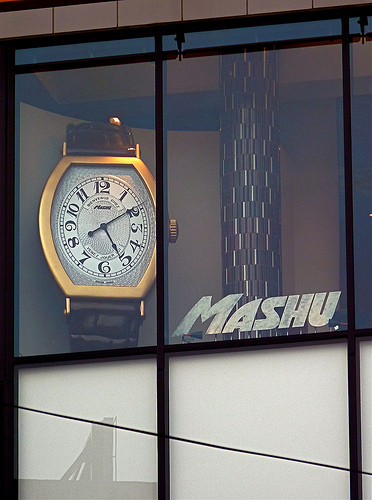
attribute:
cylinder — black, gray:
[216, 50, 283, 340]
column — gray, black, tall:
[220, 49, 284, 337]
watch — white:
[38, 120, 180, 352]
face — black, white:
[51, 164, 155, 286]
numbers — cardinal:
[64, 178, 143, 274]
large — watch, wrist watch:
[39, 120, 179, 344]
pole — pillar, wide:
[220, 34, 283, 348]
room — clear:
[10, 47, 372, 356]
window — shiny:
[11, 3, 367, 498]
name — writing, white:
[167, 292, 346, 334]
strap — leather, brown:
[63, 123, 138, 155]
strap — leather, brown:
[70, 309, 139, 349]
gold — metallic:
[39, 153, 180, 300]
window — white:
[14, 340, 350, 499]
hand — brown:
[89, 201, 142, 258]